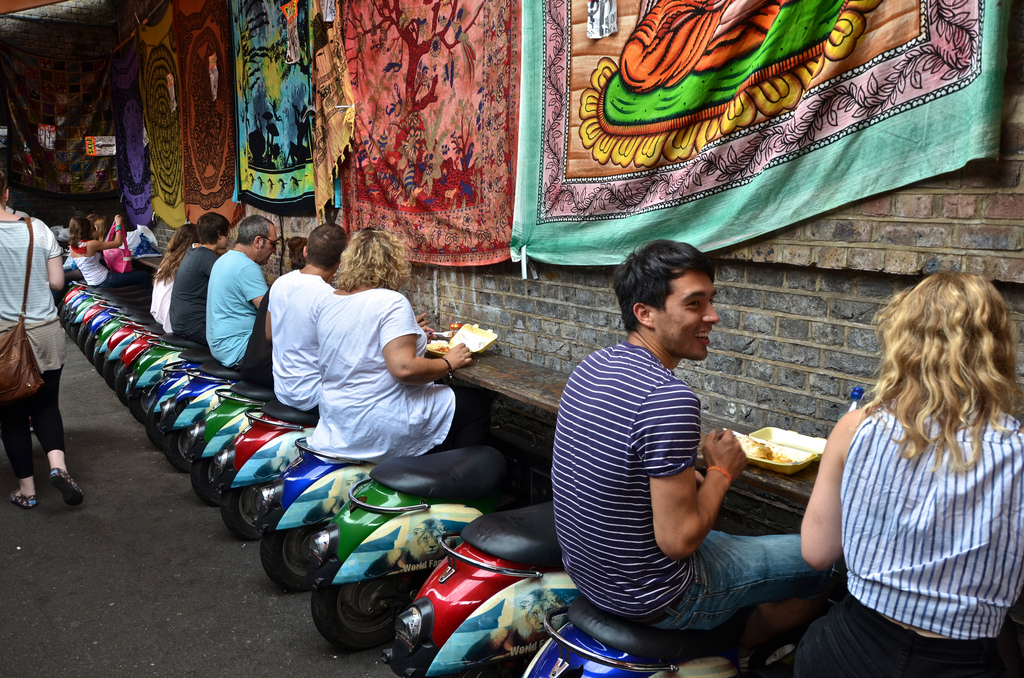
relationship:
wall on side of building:
[127, 3, 1015, 675] [4, 9, 1018, 675]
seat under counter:
[460, 485, 577, 578] [121, 227, 1020, 603]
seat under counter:
[460, 485, 577, 578] [265, 277, 1020, 636]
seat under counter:
[360, 433, 507, 518] [226, 266, 1020, 614]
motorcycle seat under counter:
[138, 357, 208, 457] [121, 245, 858, 516]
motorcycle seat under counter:
[194, 413, 294, 539] [267, 257, 914, 567]